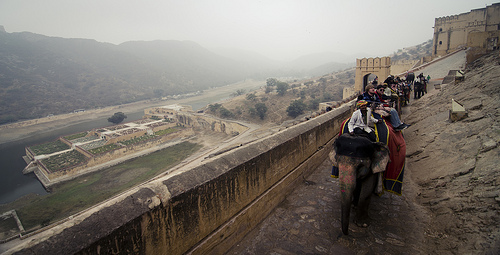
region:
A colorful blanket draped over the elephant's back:
[332, 112, 403, 195]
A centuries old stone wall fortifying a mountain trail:
[2, 48, 469, 252]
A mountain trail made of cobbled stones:
[227, 76, 444, 253]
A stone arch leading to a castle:
[355, 57, 391, 97]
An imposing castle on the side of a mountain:
[432, 4, 497, 61]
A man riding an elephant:
[346, 101, 380, 136]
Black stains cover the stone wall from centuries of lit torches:
[20, 104, 352, 251]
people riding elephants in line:
[333, 73, 404, 232]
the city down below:
[10, 117, 195, 161]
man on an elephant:
[349, 100, 375, 132]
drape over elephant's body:
[331, 118, 412, 186]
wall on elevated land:
[146, 168, 266, 225]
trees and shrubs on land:
[236, 78, 310, 113]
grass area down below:
[48, 182, 89, 206]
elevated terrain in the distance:
[0, 33, 135, 110]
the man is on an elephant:
[327, 98, 397, 214]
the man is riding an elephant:
[332, 102, 401, 242]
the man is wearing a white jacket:
[349, 105, 379, 137]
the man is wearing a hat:
[356, 97, 368, 107]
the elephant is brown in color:
[332, 122, 394, 214]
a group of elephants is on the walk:
[320, 67, 436, 233]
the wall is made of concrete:
[19, 65, 387, 253]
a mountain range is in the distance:
[3, 21, 367, 86]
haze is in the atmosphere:
[1, 0, 498, 85]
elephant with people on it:
[310, 97, 411, 219]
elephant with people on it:
[310, 94, 411, 227]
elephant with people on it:
[305, 102, 415, 227]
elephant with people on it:
[304, 102, 410, 233]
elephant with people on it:
[310, 94, 416, 230]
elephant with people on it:
[315, 109, 408, 234]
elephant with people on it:
[325, 100, 405, 233]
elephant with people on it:
[308, 98, 413, 223]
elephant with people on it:
[307, 104, 419, 232]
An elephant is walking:
[319, 128, 390, 233]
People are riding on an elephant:
[341, 93, 411, 160]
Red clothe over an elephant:
[379, 125, 414, 195]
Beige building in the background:
[430, 2, 499, 72]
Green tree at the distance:
[245, 94, 267, 129]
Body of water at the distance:
[1, 140, 58, 198]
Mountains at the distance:
[9, 21, 259, 72]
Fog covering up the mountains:
[131, 19, 268, 79]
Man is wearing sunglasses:
[375, 82, 389, 95]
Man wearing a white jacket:
[348, 108, 380, 133]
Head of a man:
[354, 96, 369, 113]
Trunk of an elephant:
[338, 179, 352, 237]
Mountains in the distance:
[13, 15, 158, 73]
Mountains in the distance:
[10, 18, 168, 64]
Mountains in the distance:
[9, 11, 126, 79]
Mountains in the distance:
[28, 18, 182, 69]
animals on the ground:
[267, 45, 482, 213]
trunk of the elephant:
[318, 171, 370, 238]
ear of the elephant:
[359, 139, 399, 180]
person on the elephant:
[322, 91, 402, 148]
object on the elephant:
[371, 112, 421, 198]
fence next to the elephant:
[187, 117, 317, 222]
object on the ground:
[413, 82, 483, 149]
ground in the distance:
[16, 76, 225, 192]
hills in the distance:
[16, 35, 221, 117]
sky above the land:
[143, 3, 293, 47]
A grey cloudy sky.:
[1, 1, 486, 53]